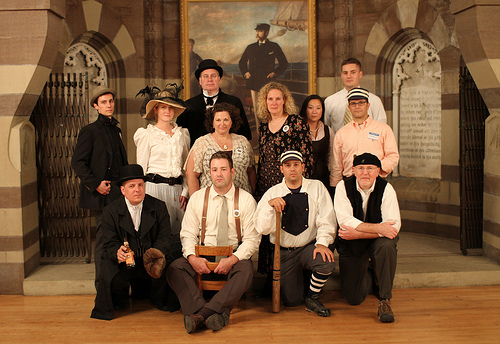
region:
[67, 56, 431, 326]
A group of 12 people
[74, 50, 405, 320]
The people are dressed in old fashioned clothes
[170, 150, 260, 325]
This guy is on a tiny chair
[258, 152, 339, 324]
This guy is leaning on a bat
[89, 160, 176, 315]
This guy is holding a beer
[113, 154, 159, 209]
He is wearing a black top hat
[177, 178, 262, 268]
This man is wearing suspenders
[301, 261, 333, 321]
He is wearing black and white striped socks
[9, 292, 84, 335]
The floor is made of hardwood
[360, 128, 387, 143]
This man is wearing a name tag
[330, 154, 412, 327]
Man wearing a black vest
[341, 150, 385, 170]
Hat on man's head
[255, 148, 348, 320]
Man kneeling on one knee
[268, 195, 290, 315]
Bat in man's hand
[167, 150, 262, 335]
Man sitting on a small chair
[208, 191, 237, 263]
Tie around the man's neck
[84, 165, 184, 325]
Man wearing a black coat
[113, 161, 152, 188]
Hat on man's head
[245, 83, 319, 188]
Woman wearing a floral dress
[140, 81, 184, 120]
Hat on woman's head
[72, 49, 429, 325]
Group of people posing for a picture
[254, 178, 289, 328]
Black and brown walking cane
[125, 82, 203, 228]
Woman in white dress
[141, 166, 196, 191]
Black belt on white dress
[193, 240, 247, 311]
Tiny brown chair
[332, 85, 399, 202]
Man wearing black and white hat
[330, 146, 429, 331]
Man wearing black hat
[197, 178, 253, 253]
Two brown suspenders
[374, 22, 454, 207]
Brown and white window arch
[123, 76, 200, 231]
Woman wearing brown and black hat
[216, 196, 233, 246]
gray neck tie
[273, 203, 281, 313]
a wooden baseball bat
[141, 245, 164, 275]
a leather baseball glove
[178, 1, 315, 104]
gold framed painting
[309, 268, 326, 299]
black socks with white stripes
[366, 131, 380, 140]
name tag on the man's shirt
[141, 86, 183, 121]
woman is wearing a fancy hat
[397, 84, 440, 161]
writing on the wall art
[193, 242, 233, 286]
small wooden chair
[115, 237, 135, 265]
man is holding a glass bottle